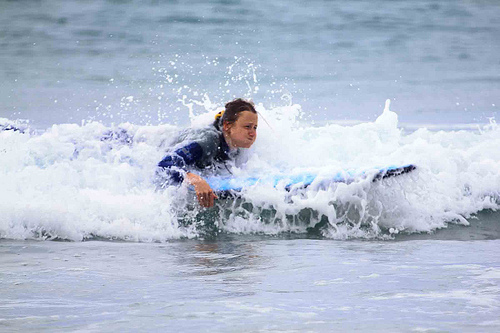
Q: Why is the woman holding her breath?
A: Water.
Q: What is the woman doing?
A: Surfing.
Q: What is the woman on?
A: Surfboard.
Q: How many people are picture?
A: 1.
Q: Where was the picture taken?
A: Ocean.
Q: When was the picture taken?
A: Afternoon.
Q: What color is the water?
A: Blue.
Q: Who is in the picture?
A: Woman.